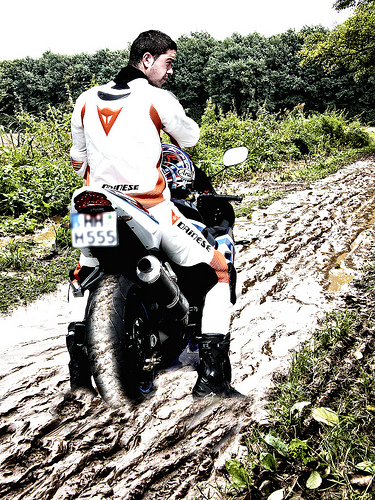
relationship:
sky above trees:
[0, 6, 367, 63] [6, 24, 373, 140]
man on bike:
[49, 26, 229, 252] [66, 144, 249, 418]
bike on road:
[66, 144, 249, 418] [2, 161, 373, 495]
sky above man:
[0, 6, 367, 63] [49, 26, 229, 252]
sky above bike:
[0, 6, 367, 63] [66, 144, 249, 418]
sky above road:
[0, 6, 367, 63] [2, 161, 373, 495]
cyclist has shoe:
[68, 30, 249, 405] [187, 326, 242, 405]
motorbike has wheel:
[60, 142, 253, 416] [81, 269, 162, 420]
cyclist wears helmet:
[60, 20, 246, 403] [171, 179, 236, 238]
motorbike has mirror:
[60, 142, 253, 416] [220, 140, 251, 171]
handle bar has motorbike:
[202, 187, 245, 206] [60, 142, 253, 416]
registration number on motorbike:
[68, 206, 117, 249] [64, 144, 249, 411]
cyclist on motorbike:
[68, 30, 249, 405] [60, 142, 253, 416]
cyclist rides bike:
[68, 30, 249, 405] [66, 144, 249, 418]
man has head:
[55, 21, 209, 181] [116, 22, 182, 92]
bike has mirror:
[66, 144, 249, 418] [220, 140, 251, 171]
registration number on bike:
[67, 206, 117, 248] [60, 138, 257, 417]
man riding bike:
[49, 26, 229, 252] [60, 138, 257, 417]